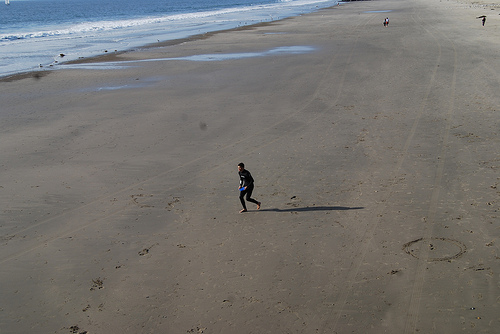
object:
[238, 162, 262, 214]
man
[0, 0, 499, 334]
beach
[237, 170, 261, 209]
wet suit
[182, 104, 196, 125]
sand